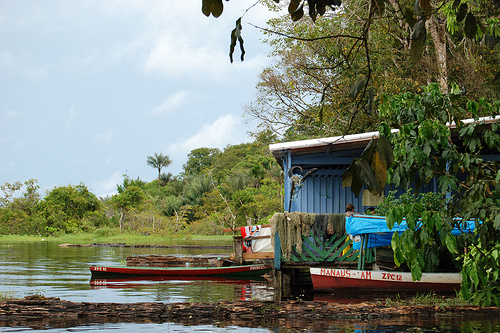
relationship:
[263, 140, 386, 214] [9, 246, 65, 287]
house on river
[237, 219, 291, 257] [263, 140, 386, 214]
dock by house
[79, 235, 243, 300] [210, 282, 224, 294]
boat on water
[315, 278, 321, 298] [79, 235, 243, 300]
paint on boat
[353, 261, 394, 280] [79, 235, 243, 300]
letters on boat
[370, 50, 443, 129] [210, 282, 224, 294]
tree near water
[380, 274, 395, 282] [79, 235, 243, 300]
number on boat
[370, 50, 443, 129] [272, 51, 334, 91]
tree has leaves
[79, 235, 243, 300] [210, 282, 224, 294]
boat in water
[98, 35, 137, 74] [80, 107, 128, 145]
sky has cloud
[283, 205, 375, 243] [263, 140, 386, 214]
clothes inside house